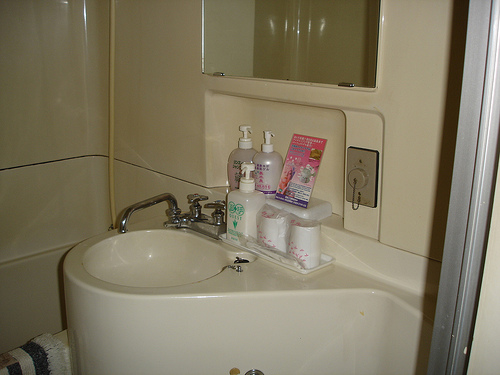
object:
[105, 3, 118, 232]
hose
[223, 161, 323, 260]
toiletries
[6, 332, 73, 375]
bath mat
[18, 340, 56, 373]
stripes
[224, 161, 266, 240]
bottle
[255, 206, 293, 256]
cup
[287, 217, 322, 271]
cup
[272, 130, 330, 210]
brochure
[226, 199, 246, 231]
writing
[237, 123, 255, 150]
pump lid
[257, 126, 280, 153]
pump lid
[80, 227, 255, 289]
basin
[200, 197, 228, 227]
handles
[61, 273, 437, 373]
wall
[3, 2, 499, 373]
bathroom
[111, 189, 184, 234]
faucet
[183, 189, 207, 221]
handle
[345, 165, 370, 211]
cover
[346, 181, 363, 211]
chain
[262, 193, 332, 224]
soap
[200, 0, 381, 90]
bathroom mirror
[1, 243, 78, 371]
tub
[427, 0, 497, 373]
doorway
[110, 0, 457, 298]
wall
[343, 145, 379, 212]
socket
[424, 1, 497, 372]
door frame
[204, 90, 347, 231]
cut out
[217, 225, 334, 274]
tray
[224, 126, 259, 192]
bathroom accessories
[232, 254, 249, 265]
drain plug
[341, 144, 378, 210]
plug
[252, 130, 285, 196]
bottle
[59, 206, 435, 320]
counter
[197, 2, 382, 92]
mirror